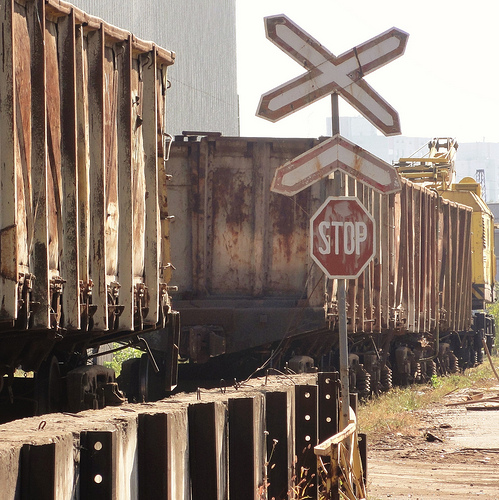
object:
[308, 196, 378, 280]
stop sign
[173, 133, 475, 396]
box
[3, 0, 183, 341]
box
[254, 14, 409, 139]
sign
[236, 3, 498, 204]
sky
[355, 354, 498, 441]
grass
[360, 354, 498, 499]
ground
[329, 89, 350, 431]
pole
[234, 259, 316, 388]
wire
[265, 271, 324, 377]
wire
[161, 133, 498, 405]
train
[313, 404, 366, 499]
fence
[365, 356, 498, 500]
road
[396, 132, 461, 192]
machine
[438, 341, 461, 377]
wheel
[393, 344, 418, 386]
wheel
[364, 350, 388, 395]
wheel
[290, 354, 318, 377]
wheel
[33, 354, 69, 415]
wheel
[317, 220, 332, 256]
letter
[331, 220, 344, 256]
letter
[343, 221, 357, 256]
letter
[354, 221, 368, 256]
letter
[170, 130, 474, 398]
train car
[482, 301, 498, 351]
weeds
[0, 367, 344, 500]
wall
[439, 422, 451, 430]
rock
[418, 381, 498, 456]
asphalt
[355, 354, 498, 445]
patch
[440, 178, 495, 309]
head